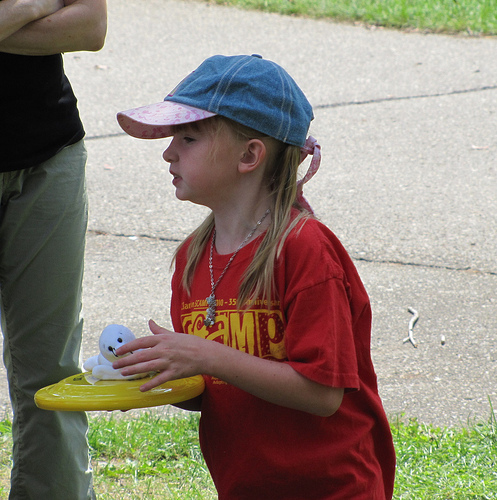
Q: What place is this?
A: It is a road.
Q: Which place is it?
A: It is a road.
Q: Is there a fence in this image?
A: No, there are no fences.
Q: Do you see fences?
A: No, there are no fences.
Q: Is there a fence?
A: No, there are no fences.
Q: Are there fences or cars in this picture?
A: No, there are no fences or cars.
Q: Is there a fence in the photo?
A: No, there are no fences.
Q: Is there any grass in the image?
A: Yes, there is grass.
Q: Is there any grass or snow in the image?
A: Yes, there is grass.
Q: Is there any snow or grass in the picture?
A: Yes, there is grass.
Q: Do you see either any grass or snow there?
A: Yes, there is grass.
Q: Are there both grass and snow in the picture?
A: No, there is grass but no snow.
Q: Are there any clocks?
A: No, there are no clocks.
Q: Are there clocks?
A: No, there are no clocks.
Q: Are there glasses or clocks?
A: No, there are no clocks or glasses.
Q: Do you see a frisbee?
A: Yes, there is a frisbee.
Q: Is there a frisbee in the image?
A: Yes, there is a frisbee.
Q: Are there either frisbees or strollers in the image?
A: Yes, there is a frisbee.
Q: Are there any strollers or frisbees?
A: Yes, there is a frisbee.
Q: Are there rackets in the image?
A: No, there are no rackets.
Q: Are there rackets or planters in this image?
A: No, there are no rackets or planters.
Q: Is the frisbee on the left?
A: Yes, the frisbee is on the left of the image.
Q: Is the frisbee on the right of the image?
A: No, the frisbee is on the left of the image.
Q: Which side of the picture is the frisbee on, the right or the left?
A: The frisbee is on the left of the image.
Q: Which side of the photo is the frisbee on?
A: The frisbee is on the left of the image.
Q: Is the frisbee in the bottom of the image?
A: Yes, the frisbee is in the bottom of the image.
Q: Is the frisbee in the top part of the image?
A: No, the frisbee is in the bottom of the image.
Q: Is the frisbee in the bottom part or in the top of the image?
A: The frisbee is in the bottom of the image.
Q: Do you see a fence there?
A: No, there are no fences.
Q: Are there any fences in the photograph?
A: No, there are no fences.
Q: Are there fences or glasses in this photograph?
A: No, there are no fences or glasses.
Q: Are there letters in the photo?
A: Yes, there are letters.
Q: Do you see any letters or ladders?
A: Yes, there are letters.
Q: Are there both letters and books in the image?
A: No, there are letters but no books.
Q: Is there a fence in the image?
A: No, there are no fences.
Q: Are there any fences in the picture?
A: No, there are no fences.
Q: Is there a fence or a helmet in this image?
A: No, there are no fences or helmets.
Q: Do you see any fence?
A: No, there are no fences.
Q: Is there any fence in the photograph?
A: No, there are no fences.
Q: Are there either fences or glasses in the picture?
A: No, there are no fences or glasses.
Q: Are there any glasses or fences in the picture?
A: No, there are no fences or glasses.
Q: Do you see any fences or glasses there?
A: No, there are no fences or glasses.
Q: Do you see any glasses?
A: No, there are no glasses.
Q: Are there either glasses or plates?
A: No, there are no glasses or plates.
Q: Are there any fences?
A: No, there are no fences.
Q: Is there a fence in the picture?
A: No, there are no fences.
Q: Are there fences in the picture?
A: No, there are no fences.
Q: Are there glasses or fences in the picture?
A: No, there are no fences or glasses.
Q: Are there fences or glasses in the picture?
A: No, there are no fences or glasses.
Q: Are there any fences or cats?
A: No, there are no fences or cats.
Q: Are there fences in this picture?
A: No, there are no fences.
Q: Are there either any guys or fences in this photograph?
A: No, there are no fences or guys.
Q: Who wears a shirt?
A: The girl wears a shirt.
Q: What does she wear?
A: The girl wears a shirt.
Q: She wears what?
A: The girl wears a shirt.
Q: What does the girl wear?
A: The girl wears a shirt.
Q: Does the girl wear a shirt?
A: Yes, the girl wears a shirt.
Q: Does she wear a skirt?
A: No, the girl wears a shirt.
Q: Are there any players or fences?
A: No, there are no fences or players.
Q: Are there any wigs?
A: No, there are no wigs.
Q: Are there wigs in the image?
A: No, there are no wigs.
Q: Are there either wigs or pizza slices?
A: No, there are no wigs or pizza slices.